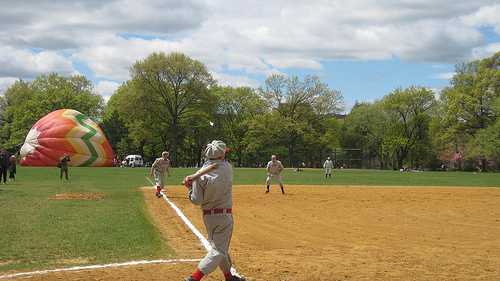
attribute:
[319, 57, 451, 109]
blue sky — clear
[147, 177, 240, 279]
white line — chalk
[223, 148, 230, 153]
brim — red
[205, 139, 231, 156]
hat — grey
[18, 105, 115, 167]
balloon — hot air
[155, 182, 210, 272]
line — white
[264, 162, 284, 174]
shirt — white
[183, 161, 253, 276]
baseball uniform — white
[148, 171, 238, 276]
line — painted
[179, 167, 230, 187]
baseball bat — wooden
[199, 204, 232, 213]
belt — red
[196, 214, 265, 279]
pant — grey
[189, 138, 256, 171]
hat — grey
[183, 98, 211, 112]
leaves — green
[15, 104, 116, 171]
balloon — deflating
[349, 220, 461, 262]
dirt — brown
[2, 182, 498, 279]
dirt — brown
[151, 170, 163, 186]
pant — grey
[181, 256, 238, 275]
socks — red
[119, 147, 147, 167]
van — white